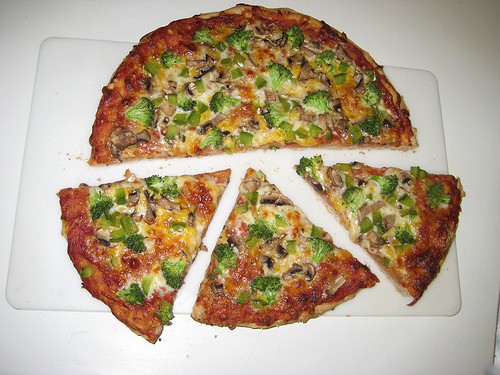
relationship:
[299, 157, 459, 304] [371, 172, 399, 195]
pizza with broccoli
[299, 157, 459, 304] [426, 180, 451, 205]
pizza with broccoli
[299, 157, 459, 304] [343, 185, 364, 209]
pizza with broccoli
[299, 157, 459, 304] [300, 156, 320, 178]
pizza with broccoli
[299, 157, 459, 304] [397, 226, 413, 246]
pizza with broccoli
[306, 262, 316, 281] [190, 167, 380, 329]
mushroom on pizza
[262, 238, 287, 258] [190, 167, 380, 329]
mushroom on pizza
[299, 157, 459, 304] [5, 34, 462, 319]
pizza on cutting board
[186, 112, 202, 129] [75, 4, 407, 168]
bell pepper on pizza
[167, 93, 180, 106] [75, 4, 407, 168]
bell pepper on pizza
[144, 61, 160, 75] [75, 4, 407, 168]
bell pepper on pizza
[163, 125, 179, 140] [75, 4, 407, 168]
bell pepper on pizza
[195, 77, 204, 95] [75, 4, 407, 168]
bell pepper on pizza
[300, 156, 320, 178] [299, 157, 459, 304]
broccoli on pizza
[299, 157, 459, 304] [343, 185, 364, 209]
pizza has broccoli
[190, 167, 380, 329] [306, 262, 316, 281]
pizza has mushroom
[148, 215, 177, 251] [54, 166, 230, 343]
cheese on pizza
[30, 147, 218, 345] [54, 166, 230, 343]
slice of pizza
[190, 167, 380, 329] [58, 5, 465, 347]
slice of pizza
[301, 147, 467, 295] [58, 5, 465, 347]
slice of pizza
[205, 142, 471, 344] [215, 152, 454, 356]
slices of pizza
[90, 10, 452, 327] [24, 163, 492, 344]
pizza cut into slices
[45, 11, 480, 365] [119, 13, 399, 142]
picture of pizza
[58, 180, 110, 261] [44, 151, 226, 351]
crunchy part of pizza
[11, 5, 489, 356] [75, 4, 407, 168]
pieces of pizza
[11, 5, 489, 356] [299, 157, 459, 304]
pieces of pizza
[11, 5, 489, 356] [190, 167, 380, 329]
pieces of pizza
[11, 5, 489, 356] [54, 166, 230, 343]
pieces of pizza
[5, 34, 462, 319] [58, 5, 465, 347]
cutting board for pizza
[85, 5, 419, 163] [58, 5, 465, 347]
half of pizza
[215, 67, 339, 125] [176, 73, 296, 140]
broccoli and mushrooms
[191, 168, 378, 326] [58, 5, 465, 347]
crust of pizza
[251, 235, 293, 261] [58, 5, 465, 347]
mushroom on pizza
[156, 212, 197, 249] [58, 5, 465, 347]
cheese on pizza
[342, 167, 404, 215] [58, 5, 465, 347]
broccoli on pizza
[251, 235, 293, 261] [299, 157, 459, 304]
mushroom on pizza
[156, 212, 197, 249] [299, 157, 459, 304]
cheese on pizza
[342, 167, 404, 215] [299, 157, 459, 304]
broccoli on pizza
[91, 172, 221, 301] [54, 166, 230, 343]
cheese on pizza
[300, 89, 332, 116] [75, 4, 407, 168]
vegetable on pizza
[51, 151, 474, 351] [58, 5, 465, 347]
slices of pizza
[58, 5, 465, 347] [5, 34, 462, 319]
pizza on cutting board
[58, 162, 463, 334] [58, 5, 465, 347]
half of pizza